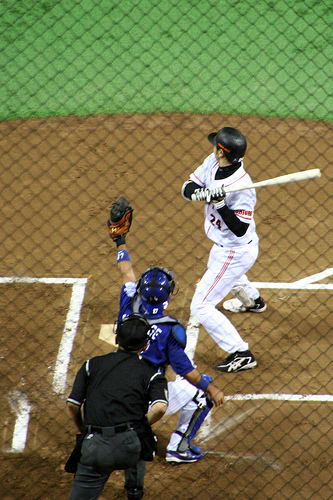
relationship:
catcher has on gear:
[109, 200, 225, 462] [130, 268, 189, 348]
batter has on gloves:
[181, 127, 267, 373] [212, 185, 226, 201]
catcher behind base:
[108, 199, 136, 285] [98, 324, 119, 348]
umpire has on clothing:
[67, 317, 163, 500] [71, 351, 169, 499]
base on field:
[98, 324, 119, 348] [2, 3, 333, 126]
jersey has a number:
[117, 285, 194, 375] [210, 213, 222, 232]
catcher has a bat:
[109, 200, 225, 462] [191, 168, 322, 203]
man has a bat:
[186, 124, 267, 375] [188, 168, 323, 201]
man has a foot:
[186, 124, 267, 375] [219, 351, 258, 372]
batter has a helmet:
[181, 127, 267, 373] [208, 129, 245, 162]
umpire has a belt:
[67, 317, 163, 500] [83, 424, 140, 434]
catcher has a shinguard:
[109, 200, 225, 462] [179, 391, 208, 460]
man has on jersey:
[186, 124, 267, 375] [117, 285, 194, 375]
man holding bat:
[186, 124, 267, 375] [188, 168, 323, 201]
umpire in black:
[67, 317, 163, 500] [67, 320, 157, 500]